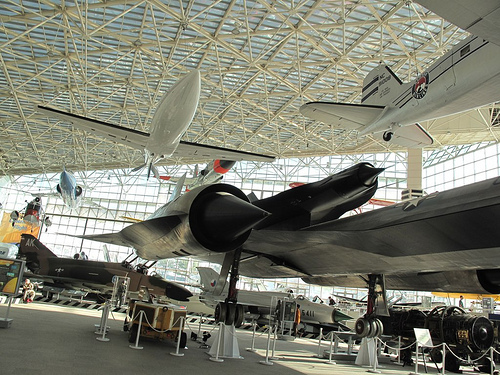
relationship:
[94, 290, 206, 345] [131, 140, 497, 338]
stanchions surround exhibits